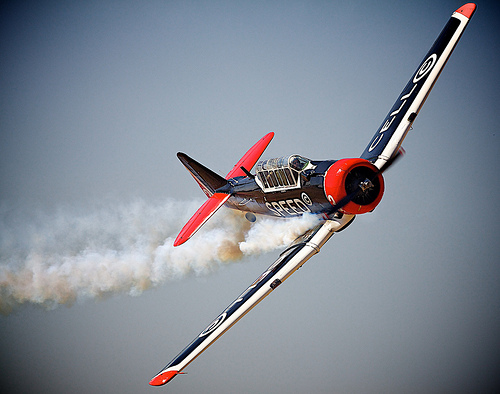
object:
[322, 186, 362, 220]
blades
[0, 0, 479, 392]
tricks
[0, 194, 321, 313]
smoke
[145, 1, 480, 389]
plane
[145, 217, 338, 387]
wing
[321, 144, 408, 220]
propeller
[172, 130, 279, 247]
tail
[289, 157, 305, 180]
pilot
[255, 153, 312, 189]
windows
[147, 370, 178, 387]
wing tip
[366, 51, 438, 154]
print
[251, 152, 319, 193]
cockpit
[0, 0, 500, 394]
sky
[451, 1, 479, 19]
wing tip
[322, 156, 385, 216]
nose